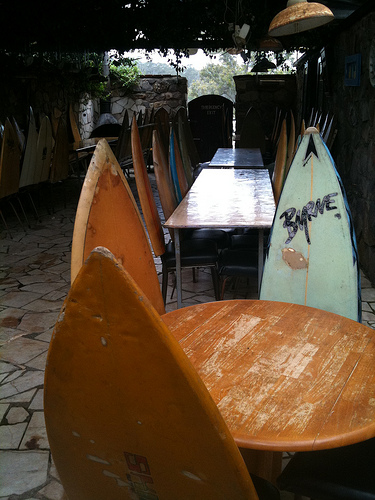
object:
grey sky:
[104, 49, 302, 89]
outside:
[104, 42, 322, 82]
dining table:
[161, 146, 277, 309]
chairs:
[130, 105, 228, 308]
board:
[257, 126, 361, 323]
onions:
[13, 231, 56, 330]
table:
[159, 299, 374, 451]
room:
[0, 46, 375, 500]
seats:
[129, 113, 224, 309]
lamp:
[268, 0, 334, 37]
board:
[168, 116, 195, 203]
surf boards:
[124, 108, 200, 255]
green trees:
[186, 53, 249, 98]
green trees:
[136, 58, 196, 85]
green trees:
[95, 57, 138, 91]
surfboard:
[257, 126, 361, 324]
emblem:
[302, 133, 321, 167]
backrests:
[70, 137, 167, 315]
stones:
[0, 208, 71, 337]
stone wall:
[2, 75, 187, 144]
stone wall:
[232, 3, 374, 286]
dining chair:
[257, 126, 361, 322]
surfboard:
[127, 115, 167, 260]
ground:
[0, 168, 375, 500]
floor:
[0, 173, 375, 500]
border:
[170, 123, 183, 204]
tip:
[299, 126, 325, 143]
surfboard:
[69, 139, 165, 317]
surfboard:
[42, 243, 260, 499]